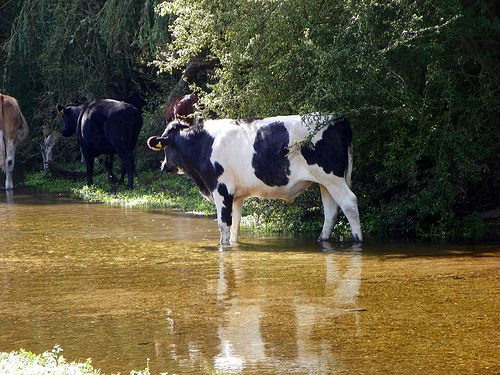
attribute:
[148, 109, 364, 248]
cow — spotted, black, white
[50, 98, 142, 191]
cow — black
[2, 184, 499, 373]
water — shallow, still, calm, placid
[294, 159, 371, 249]
legs — short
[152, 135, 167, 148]
peg — yellow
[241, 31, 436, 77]
leaves — green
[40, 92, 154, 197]
cow — fat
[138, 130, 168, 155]
ear — big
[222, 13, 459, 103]
leaves — green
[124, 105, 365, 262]
bull — black, white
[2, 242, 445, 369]
water — muddy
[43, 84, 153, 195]
bull — black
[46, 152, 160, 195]
grass — green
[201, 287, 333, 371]
reflection — bull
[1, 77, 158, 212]
silver bills — in the shade, cool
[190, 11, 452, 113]
bush — pretty, green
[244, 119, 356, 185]
spots — black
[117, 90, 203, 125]
bull — brown, hiding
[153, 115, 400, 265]
cow — black, white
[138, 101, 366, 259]
cow — white, Black, standing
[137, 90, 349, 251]
cow — standing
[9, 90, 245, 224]
cows — drinking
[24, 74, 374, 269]
cows — absorbing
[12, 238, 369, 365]
water — yellow, dirty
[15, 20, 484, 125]
trees — surrounding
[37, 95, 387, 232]
cows — standing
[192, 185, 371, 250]
legs — reflected